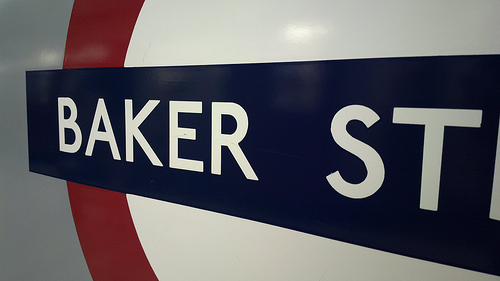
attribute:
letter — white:
[203, 98, 270, 186]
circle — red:
[45, 3, 210, 278]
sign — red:
[0, 1, 499, 277]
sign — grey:
[26, 53, 498, 273]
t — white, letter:
[392, 97, 492, 217]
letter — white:
[55, 95, 82, 155]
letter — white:
[390, 104, 484, 214]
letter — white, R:
[210, 99, 261, 184]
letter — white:
[168, 100, 202, 175]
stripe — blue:
[26, 52, 499, 279]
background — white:
[2, 2, 497, 279]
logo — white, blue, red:
[13, 38, 499, 279]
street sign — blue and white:
[24, 51, 499, 278]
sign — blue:
[28, 55, 388, 242]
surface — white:
[31, 29, 466, 256]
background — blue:
[25, 70, 499, 95]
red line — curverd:
[59, 1, 169, 278]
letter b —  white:
[55, 96, 82, 153]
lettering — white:
[57, 96, 259, 181]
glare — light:
[11, 10, 363, 156]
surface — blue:
[29, 70, 484, 235]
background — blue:
[26, 70, 483, 218]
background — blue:
[31, 72, 483, 242]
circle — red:
[57, 1, 164, 278]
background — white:
[136, 12, 354, 277]